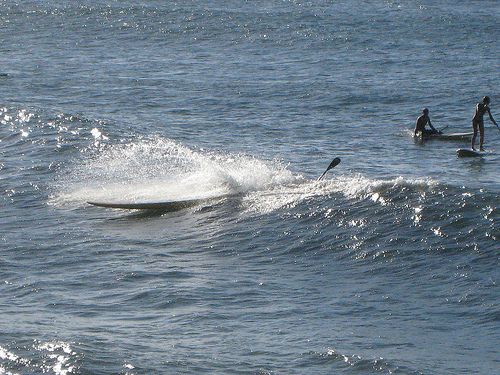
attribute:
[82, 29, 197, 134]
water — deep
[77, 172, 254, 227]
surfboard — empty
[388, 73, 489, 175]
woman — skinny